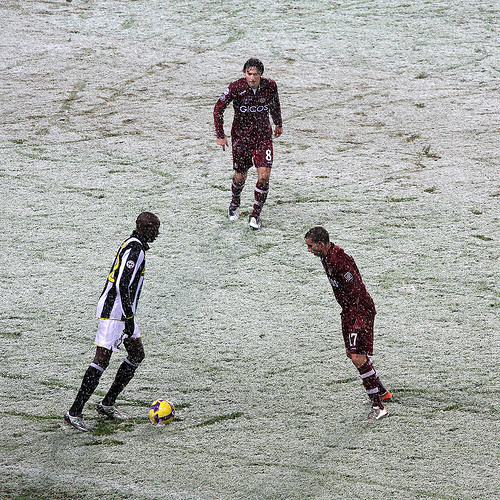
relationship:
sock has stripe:
[363, 361, 390, 401] [377, 388, 388, 399]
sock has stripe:
[354, 358, 385, 406] [357, 364, 375, 380]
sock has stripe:
[354, 358, 385, 406] [366, 384, 379, 397]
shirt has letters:
[207, 82, 294, 164] [233, 101, 275, 116]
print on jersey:
[92, 232, 139, 272] [96, 236, 147, 321]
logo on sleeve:
[214, 82, 233, 106] [201, 80, 239, 146]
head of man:
[294, 215, 336, 260] [300, 217, 396, 427]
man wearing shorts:
[78, 172, 161, 434] [89, 302, 133, 374]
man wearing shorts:
[211, 54, 289, 225] [230, 127, 275, 172]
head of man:
[136, 212, 160, 243] [61, 199, 233, 420]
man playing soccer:
[213, 57, 283, 230] [144, 394, 181, 430]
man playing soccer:
[78, 172, 161, 434] [144, 394, 181, 430]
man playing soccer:
[304, 226, 392, 422] [144, 394, 181, 430]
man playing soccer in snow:
[213, 57, 283, 230] [1, 1, 493, 489]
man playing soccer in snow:
[304, 226, 392, 422] [1, 1, 493, 489]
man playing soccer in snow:
[78, 172, 161, 434] [1, 1, 493, 489]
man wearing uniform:
[285, 221, 418, 436] [316, 249, 388, 361]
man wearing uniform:
[78, 172, 161, 434] [87, 230, 176, 336]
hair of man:
[238, 50, 269, 69] [202, 47, 299, 237]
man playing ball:
[78, 172, 161, 434] [149, 399, 176, 425]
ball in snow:
[149, 399, 176, 425] [188, 272, 278, 399]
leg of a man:
[226, 151, 248, 217] [213, 57, 283, 230]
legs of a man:
[338, 318, 395, 420] [78, 172, 161, 434]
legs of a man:
[226, 134, 273, 230] [213, 57, 283, 230]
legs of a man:
[64, 313, 145, 434] [304, 226, 392, 422]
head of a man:
[132, 213, 162, 240] [78, 172, 161, 434]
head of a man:
[235, 52, 267, 89] [208, 52, 285, 234]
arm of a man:
[117, 238, 139, 345] [78, 172, 161, 434]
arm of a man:
[334, 247, 369, 343] [304, 226, 392, 422]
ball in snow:
[149, 399, 176, 425] [196, 234, 259, 383]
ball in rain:
[149, 399, 176, 425] [1, 6, 488, 493]